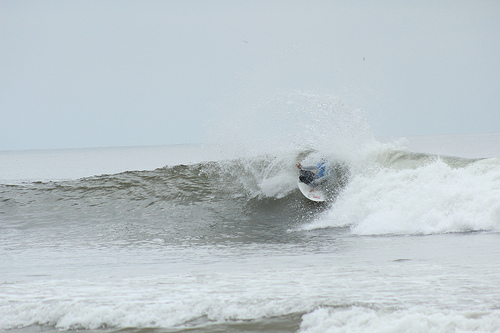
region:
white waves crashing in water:
[378, 208, 399, 228]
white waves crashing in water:
[196, 194, 221, 212]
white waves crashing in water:
[466, 208, 499, 225]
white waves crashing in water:
[450, 202, 476, 225]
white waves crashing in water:
[382, 205, 399, 220]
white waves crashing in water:
[166, 267, 198, 304]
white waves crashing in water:
[274, 254, 306, 277]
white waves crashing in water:
[386, 204, 411, 235]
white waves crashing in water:
[197, 260, 234, 300]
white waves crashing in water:
[375, 190, 438, 222]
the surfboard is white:
[291, 168, 331, 213]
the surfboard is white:
[291, 144, 320, 202]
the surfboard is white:
[281, 140, 333, 235]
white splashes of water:
[301, 171, 406, 261]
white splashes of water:
[321, 178, 392, 244]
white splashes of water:
[249, 138, 324, 205]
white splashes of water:
[320, 140, 436, 267]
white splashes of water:
[213, 130, 335, 244]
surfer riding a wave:
[285, 150, 342, 212]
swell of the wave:
[4, 178, 296, 249]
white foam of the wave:
[332, 165, 498, 239]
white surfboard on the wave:
[298, 183, 328, 206]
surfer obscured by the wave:
[291, 157, 333, 184]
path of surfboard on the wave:
[245, 163, 295, 203]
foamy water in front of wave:
[7, 251, 498, 332]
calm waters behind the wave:
[1, 151, 252, 178]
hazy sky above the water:
[8, 12, 466, 144]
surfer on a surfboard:
[287, 127, 330, 210]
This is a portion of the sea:
[15, 161, 122, 223]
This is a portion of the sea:
[105, 222, 214, 290]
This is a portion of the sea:
[257, 170, 333, 247]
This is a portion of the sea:
[353, 163, 424, 217]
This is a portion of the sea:
[47, 272, 165, 331]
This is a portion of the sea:
[348, 270, 475, 331]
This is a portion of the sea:
[108, 216, 303, 328]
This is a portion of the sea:
[40, 134, 209, 253]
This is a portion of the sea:
[328, 139, 470, 240]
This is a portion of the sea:
[34, 240, 166, 322]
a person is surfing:
[275, 143, 344, 232]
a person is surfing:
[248, 125, 373, 235]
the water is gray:
[61, 186, 268, 263]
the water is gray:
[190, 170, 294, 255]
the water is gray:
[151, 189, 278, 257]